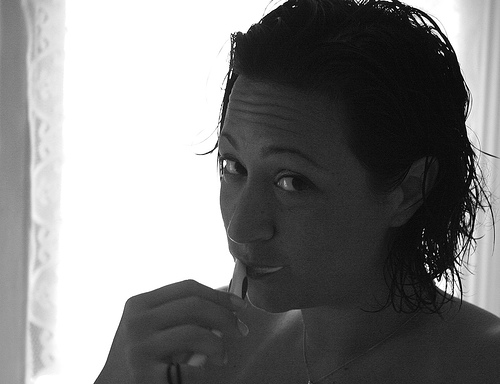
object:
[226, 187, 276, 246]
nose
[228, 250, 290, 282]
mouth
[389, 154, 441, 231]
ear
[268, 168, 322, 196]
eye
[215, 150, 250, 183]
eye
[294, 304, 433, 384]
necklace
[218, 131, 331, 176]
eyebrows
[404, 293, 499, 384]
shoulder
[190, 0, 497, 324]
hair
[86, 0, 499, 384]
girl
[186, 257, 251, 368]
toothbrush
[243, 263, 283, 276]
toothpaste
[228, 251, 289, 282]
lip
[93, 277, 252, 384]
hand